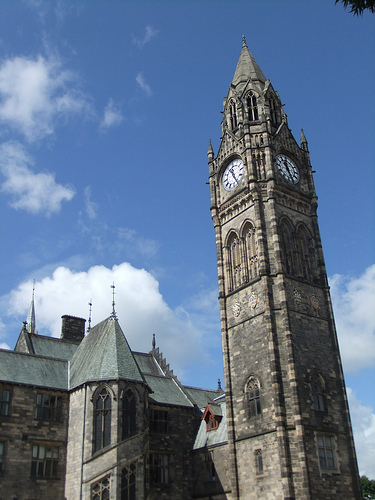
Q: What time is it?
A: Afternoon.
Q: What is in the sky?
A: Clouds.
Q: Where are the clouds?
A: In the sky.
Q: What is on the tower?
A: A clock.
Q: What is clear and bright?
A: The sky.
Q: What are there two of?
A: Clock faces.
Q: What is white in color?
A: Face of the clock.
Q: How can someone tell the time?
A: Clocks.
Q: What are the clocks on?
A: Tower.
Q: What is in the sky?
A: Clouds.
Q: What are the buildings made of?
A: Brick.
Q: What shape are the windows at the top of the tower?
A: Arched.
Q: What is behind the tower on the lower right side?
A: Tree.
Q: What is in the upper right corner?
A: Leaves.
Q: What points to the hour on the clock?
A: Hour hand.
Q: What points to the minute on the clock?
A: Minute hand.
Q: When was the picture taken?
A: Daytime.